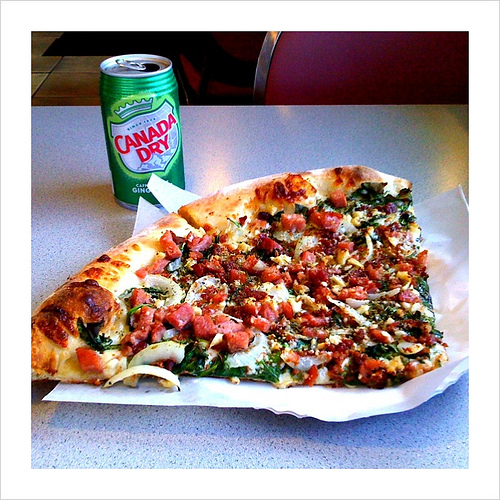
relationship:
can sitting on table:
[94, 49, 189, 211] [42, 100, 459, 457]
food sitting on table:
[31, 166, 446, 386] [42, 100, 459, 457]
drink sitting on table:
[100, 49, 188, 212] [42, 100, 459, 457]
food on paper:
[31, 166, 446, 391] [35, 170, 475, 430]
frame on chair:
[250, 30, 284, 105] [251, 31, 469, 106]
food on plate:
[31, 166, 446, 391] [242, 386, 354, 421]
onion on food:
[104, 363, 182, 393] [31, 166, 446, 391]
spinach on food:
[170, 335, 287, 382] [31, 166, 446, 391]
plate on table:
[39, 167, 466, 424] [42, 100, 459, 457]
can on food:
[94, 49, 189, 211] [31, 166, 446, 391]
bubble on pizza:
[57, 276, 117, 330] [69, 152, 456, 421]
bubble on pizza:
[258, 169, 314, 212] [69, 152, 456, 421]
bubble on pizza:
[330, 163, 383, 202] [69, 152, 456, 421]